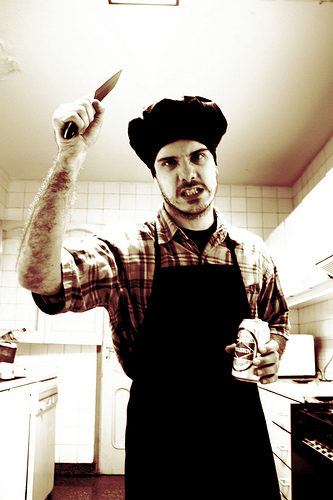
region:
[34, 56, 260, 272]
a man holding a knife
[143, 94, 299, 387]
a man holding a can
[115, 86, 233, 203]
a man wearing a hat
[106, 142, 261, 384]
a man wearing a apron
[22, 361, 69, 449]
a white dish washer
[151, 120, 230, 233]
a man with his mouth open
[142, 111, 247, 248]
a man wearing a black tee shirt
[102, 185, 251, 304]
a man wearing a plaid shirt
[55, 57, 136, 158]
a knife with a black handle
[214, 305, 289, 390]
a can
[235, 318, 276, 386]
soda can on left hand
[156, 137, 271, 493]
Drunk angry man wielding knife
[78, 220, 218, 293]
Plaid shirt on man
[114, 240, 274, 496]
Black cooking apron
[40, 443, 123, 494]
red kitchen floor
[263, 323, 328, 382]
White microwave on counter in background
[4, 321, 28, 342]
Clear plastic bottle on counter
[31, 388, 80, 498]
White dishwasher in kitchen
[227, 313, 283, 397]
Aluminum beer can in hand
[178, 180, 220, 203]
Mustache and clenched teeth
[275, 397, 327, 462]
Black stove top on right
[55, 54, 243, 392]
the man is holding a knife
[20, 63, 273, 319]
scowling man with knife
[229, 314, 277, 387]
can in man's hand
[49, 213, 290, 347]
short sleeve plaid shirt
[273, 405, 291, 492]
three handles on drawers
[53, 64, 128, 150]
knife in man's hand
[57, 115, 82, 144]
end of knife handle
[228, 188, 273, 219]
sqare tiles on wall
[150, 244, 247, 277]
two ties on apron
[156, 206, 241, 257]
open collar on shirt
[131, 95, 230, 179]
chef hat on head